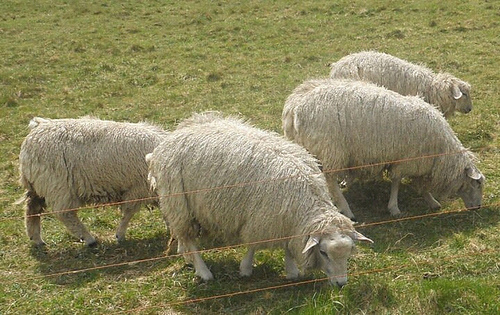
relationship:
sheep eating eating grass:
[281, 92, 491, 228] [94, 63, 498, 309]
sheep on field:
[145, 110, 375, 288] [90, 17, 266, 116]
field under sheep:
[3, 0, 495, 311] [145, 110, 375, 288]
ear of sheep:
[342, 227, 374, 243] [145, 110, 375, 288]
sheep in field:
[145, 110, 375, 288] [3, 0, 495, 311]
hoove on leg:
[84, 237, 101, 249] [47, 196, 99, 247]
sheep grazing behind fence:
[281, 70, 492, 228] [3, 130, 482, 311]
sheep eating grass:
[145, 110, 375, 288] [4, 2, 482, 308]